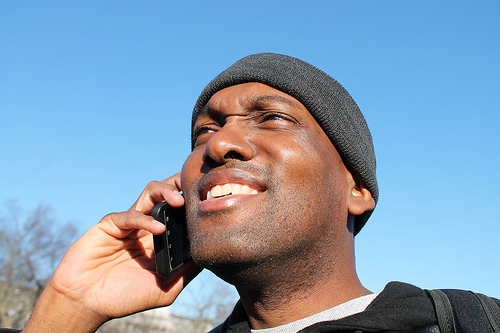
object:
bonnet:
[189, 52, 379, 235]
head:
[177, 52, 375, 272]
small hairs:
[174, 163, 339, 310]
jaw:
[183, 217, 317, 269]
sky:
[0, 0, 496, 320]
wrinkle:
[276, 121, 298, 130]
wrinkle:
[261, 124, 283, 130]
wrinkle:
[245, 112, 257, 126]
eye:
[255, 112, 299, 130]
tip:
[347, 204, 366, 214]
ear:
[346, 183, 378, 213]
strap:
[423, 289, 454, 332]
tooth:
[223, 182, 231, 193]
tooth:
[212, 183, 222, 196]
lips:
[196, 167, 269, 197]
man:
[17, 52, 498, 332]